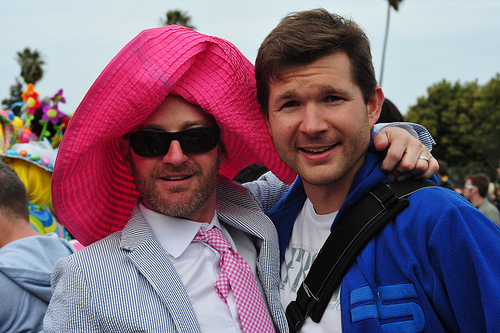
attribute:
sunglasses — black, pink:
[118, 120, 221, 160]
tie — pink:
[185, 224, 306, 331]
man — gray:
[2, 163, 79, 331]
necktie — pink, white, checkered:
[191, 225, 276, 332]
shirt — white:
[150, 212, 277, 332]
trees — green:
[406, 62, 498, 189]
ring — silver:
[414, 151, 434, 166]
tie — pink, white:
[196, 226, 288, 331]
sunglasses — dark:
[124, 121, 224, 169]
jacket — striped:
[33, 194, 301, 329]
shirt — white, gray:
[280, 204, 349, 324]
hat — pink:
[44, 19, 301, 246]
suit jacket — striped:
[53, 117, 305, 315]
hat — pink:
[39, 41, 265, 208]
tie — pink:
[192, 220, 268, 330]